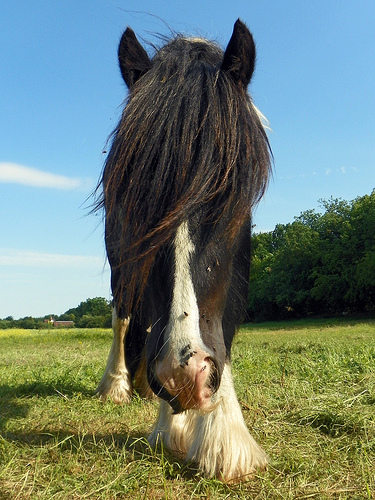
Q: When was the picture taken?
A: Daytime.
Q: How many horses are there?
A: One.